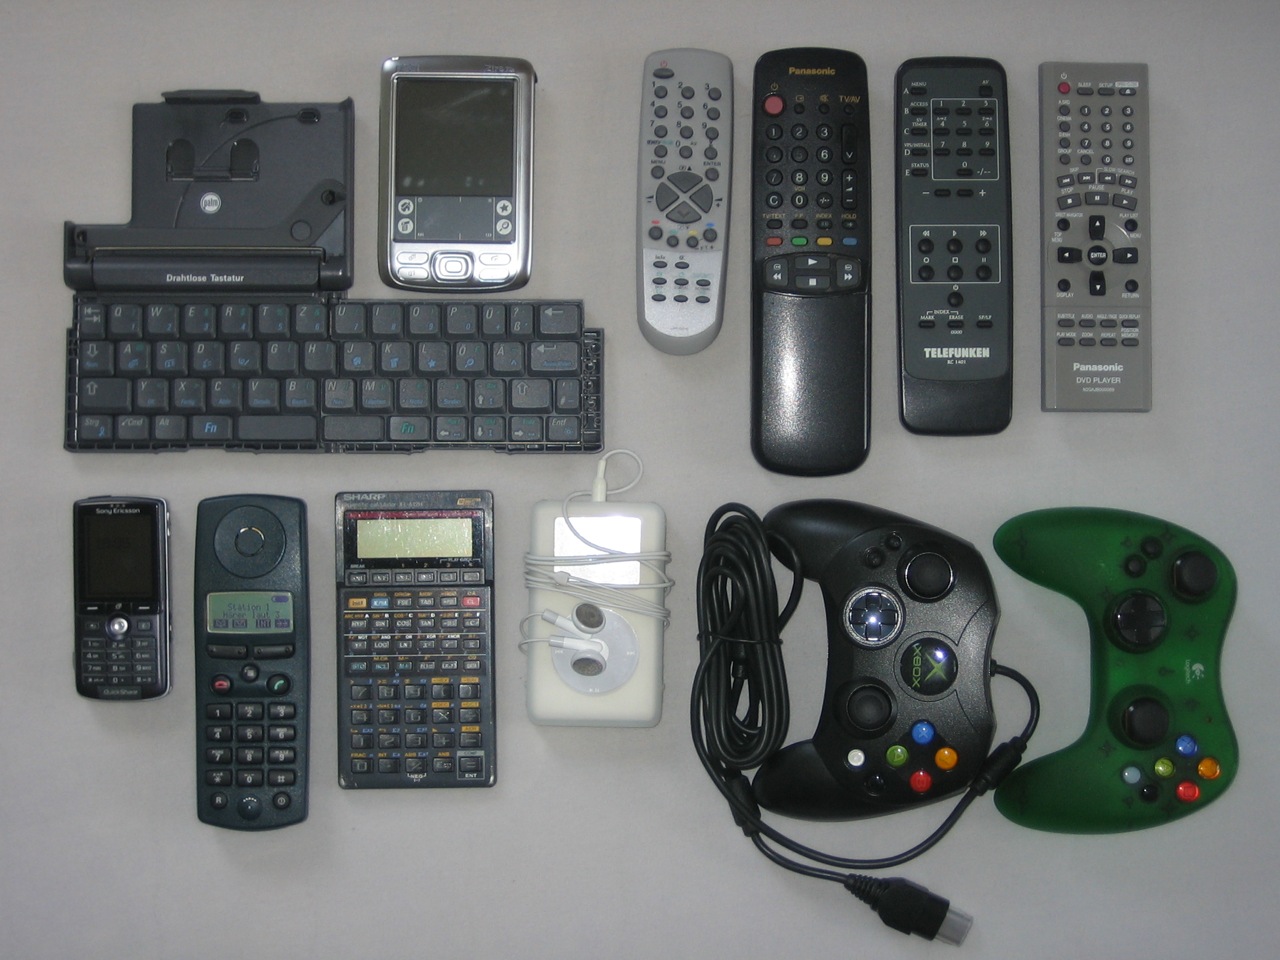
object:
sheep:
[193, 493, 311, 833]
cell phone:
[73, 495, 171, 700]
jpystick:
[992, 507, 1236, 836]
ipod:
[520, 449, 678, 728]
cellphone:
[378, 55, 539, 294]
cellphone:
[193, 493, 311, 831]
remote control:
[1038, 62, 1150, 412]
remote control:
[636, 49, 734, 356]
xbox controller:
[689, 498, 1040, 948]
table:
[0, 0, 1280, 960]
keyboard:
[65, 298, 607, 453]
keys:
[1057, 216, 1140, 297]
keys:
[650, 68, 723, 303]